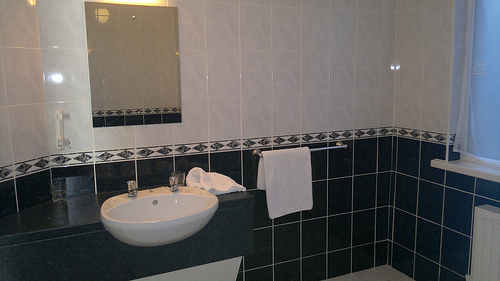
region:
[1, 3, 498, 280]
a tiled bathroom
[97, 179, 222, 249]
white porcelain sink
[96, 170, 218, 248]
two chrome taps in a sink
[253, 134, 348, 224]
white towel folded over a chrome rail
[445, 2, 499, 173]
voile covered window in a bathroom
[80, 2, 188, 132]
mirror on a tiled wall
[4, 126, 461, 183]
patterned black and white border tiles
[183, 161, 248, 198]
white face cloth on a granite shelf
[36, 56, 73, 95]
reflection of a light in some white wall tiles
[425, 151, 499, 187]
white window ledge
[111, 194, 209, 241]
this is a sink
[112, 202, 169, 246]
the sink is white in color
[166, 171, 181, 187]
this is a tap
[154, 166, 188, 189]
the tap is metallic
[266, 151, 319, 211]
this is a towel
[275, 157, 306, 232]
the towel is white in color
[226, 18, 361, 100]
this is a wall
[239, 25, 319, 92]
the wall is white in color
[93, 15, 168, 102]
this is a mirror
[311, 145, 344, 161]
this is a pipe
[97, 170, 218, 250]
A white sink bowl.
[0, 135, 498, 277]
Black tile on the lower wall.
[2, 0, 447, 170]
White marbled tile on the upper wall.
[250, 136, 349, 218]
A white towel on a metal towel rack.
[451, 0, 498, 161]
The edge of a window.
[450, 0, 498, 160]
A sheer white curtain on the window.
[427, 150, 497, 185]
A white window ledge.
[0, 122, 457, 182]
Black diamond shapes on the tile border.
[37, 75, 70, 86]
Light reflecting off of the tile.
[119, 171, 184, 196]
Two water handles on the sink.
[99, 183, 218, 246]
a white porcelain bathroom sink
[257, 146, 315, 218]
a hanging white towel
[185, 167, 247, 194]
a white crumpled towel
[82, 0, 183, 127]
a wall mounted vanity mirror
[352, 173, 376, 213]
a black wall tile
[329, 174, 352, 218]
a black wall tile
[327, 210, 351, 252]
a black wall tile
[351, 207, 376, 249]
a black wall tile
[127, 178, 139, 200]
a bathroom sink faucet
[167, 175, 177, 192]
a bathroom sink faucet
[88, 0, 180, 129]
glowing light over mirror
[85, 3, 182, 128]
reflection on wall mirror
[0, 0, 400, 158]
gray ceramic tiles on wall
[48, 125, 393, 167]
border of decorative tiles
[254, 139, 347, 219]
white towel on rack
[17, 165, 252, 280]
sing in gray vanity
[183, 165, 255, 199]
white towel on vanity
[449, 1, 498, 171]
white curtain on window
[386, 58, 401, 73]
light reflection on wall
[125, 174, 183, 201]
two knobs on sink